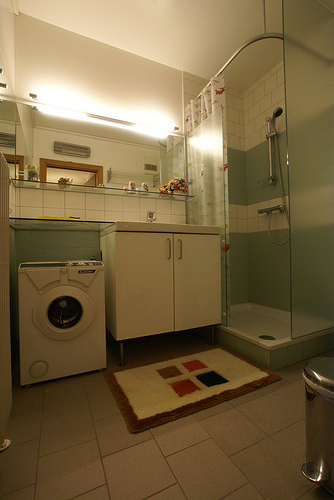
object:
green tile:
[246, 151, 253, 161]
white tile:
[243, 119, 256, 138]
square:
[196, 370, 229, 388]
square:
[169, 379, 200, 397]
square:
[156, 365, 183, 379]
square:
[181, 359, 208, 372]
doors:
[117, 232, 221, 340]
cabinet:
[99, 221, 221, 367]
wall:
[9, 126, 185, 225]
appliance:
[17, 259, 106, 386]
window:
[47, 295, 83, 330]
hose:
[267, 133, 290, 246]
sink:
[224, 302, 315, 341]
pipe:
[267, 121, 272, 178]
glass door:
[282, 0, 332, 340]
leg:
[120, 342, 123, 367]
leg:
[211, 326, 214, 346]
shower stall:
[157, 33, 334, 348]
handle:
[178, 238, 182, 260]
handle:
[167, 238, 172, 260]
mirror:
[46, 165, 99, 187]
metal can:
[301, 353, 334, 500]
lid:
[301, 353, 334, 397]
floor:
[227, 302, 332, 346]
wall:
[186, 53, 334, 319]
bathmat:
[101, 345, 283, 434]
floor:
[0, 387, 332, 497]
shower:
[272, 107, 283, 119]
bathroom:
[0, 1, 334, 500]